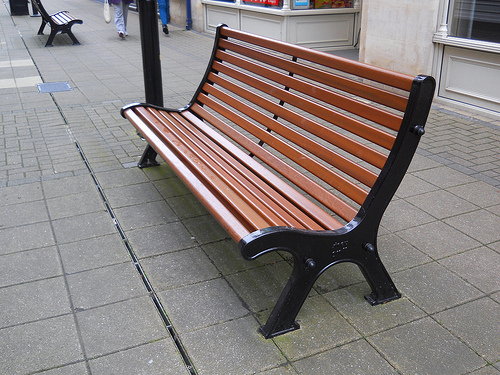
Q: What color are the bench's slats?
A: Brown.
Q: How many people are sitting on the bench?
A: 0.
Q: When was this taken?
A: Daytime.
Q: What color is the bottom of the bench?
A: Black.